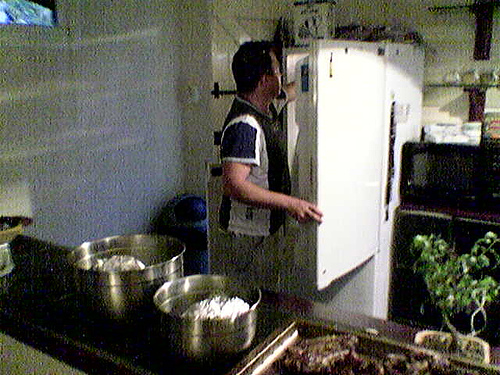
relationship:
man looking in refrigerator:
[218, 38, 298, 290] [282, 38, 424, 318]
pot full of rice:
[153, 271, 261, 355] [184, 295, 250, 323]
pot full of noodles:
[65, 230, 186, 322] [93, 254, 147, 272]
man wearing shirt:
[218, 38, 298, 290] [217, 98, 296, 237]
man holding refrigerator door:
[218, 38, 298, 290] [305, 35, 380, 290]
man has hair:
[218, 38, 298, 290] [229, 40, 273, 102]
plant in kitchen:
[408, 230, 499, 360] [4, 5, 495, 367]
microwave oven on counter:
[400, 141, 500, 215] [397, 202, 499, 229]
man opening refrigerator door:
[218, 38, 298, 290] [305, 35, 380, 290]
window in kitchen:
[2, 1, 59, 30] [4, 5, 495, 367]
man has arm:
[218, 38, 298, 290] [274, 81, 302, 113]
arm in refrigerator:
[274, 81, 302, 113] [282, 38, 424, 318]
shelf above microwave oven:
[429, 0, 496, 111] [400, 141, 500, 215]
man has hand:
[218, 38, 298, 290] [290, 193, 325, 227]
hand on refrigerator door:
[290, 193, 325, 227] [305, 35, 380, 290]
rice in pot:
[179, 295, 250, 321] [153, 271, 261, 355]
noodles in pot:
[93, 254, 147, 272] [65, 230, 186, 322]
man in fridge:
[218, 38, 298, 290] [274, 36, 424, 318]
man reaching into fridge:
[218, 38, 298, 290] [274, 36, 424, 318]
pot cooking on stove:
[153, 271, 261, 355] [29, 254, 273, 372]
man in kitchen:
[218, 38, 298, 290] [4, 5, 495, 367]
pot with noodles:
[153, 271, 261, 355] [181, 293, 248, 324]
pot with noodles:
[65, 230, 186, 322] [87, 251, 144, 276]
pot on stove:
[153, 271, 261, 355] [29, 254, 273, 372]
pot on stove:
[65, 230, 186, 322] [29, 254, 273, 372]